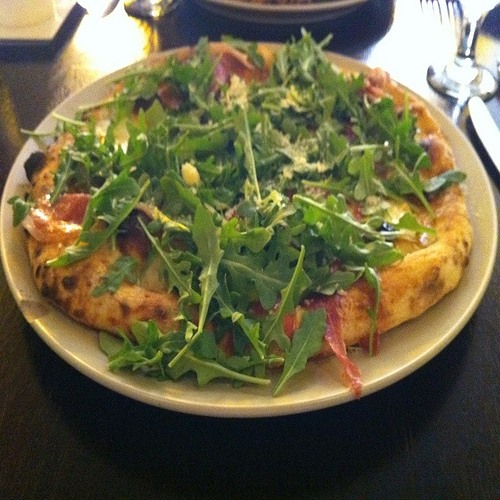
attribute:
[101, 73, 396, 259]
leaves — green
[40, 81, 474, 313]
pizza — cooked, green, white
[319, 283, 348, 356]
bacon — red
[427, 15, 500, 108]
spoon — silver, grey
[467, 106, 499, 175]
knife — silver, metal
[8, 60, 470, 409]
plate — white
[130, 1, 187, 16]
glass — white, clear